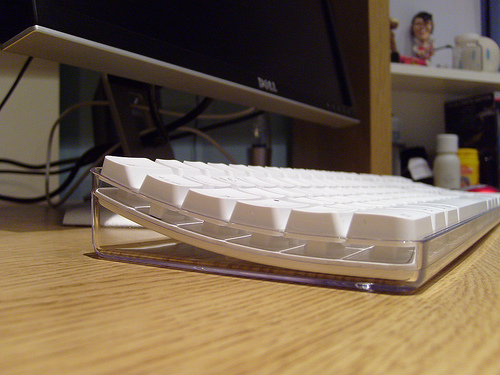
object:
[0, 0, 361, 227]
computer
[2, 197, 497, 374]
table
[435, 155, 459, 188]
label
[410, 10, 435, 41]
head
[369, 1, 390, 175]
board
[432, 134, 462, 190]
containers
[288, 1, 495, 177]
shelf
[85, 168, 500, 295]
stand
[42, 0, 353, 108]
monitor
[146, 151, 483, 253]
keys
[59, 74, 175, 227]
stand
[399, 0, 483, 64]
wall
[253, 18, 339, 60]
kite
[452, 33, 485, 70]
bottle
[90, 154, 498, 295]
keyboard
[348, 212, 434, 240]
button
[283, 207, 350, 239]
button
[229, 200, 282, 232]
button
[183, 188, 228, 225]
button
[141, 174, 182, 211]
button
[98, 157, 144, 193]
button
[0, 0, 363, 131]
frame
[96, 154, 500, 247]
board